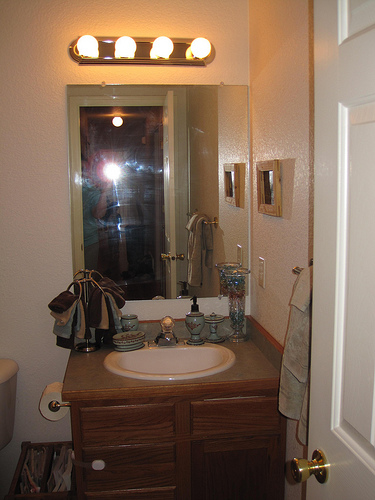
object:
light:
[72, 35, 99, 67]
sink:
[102, 339, 236, 381]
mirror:
[66, 85, 248, 299]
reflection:
[93, 147, 148, 280]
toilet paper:
[37, 383, 68, 420]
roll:
[49, 401, 62, 413]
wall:
[249, 1, 313, 378]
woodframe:
[308, 2, 314, 331]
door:
[288, 0, 374, 500]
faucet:
[156, 314, 177, 347]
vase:
[220, 266, 251, 342]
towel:
[277, 266, 310, 445]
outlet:
[256, 255, 266, 289]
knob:
[290, 448, 329, 483]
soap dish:
[113, 332, 147, 353]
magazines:
[66, 443, 73, 495]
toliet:
[0, 359, 20, 449]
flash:
[105, 160, 124, 185]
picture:
[255, 161, 284, 218]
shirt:
[115, 161, 142, 227]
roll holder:
[49, 402, 70, 411]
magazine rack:
[8, 442, 75, 498]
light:
[191, 37, 212, 61]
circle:
[191, 37, 212, 62]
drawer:
[78, 404, 176, 446]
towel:
[48, 293, 85, 312]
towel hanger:
[290, 265, 303, 276]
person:
[79, 161, 108, 275]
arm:
[89, 185, 111, 222]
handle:
[157, 316, 173, 334]